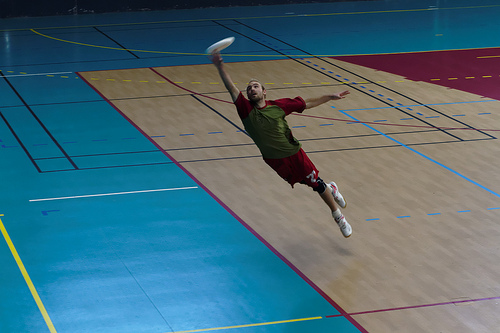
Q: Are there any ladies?
A: No, there are no ladies.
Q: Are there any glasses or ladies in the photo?
A: No, there are no ladies or glasses.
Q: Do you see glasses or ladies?
A: No, there are no ladies or glasses.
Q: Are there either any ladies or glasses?
A: No, there are no ladies or glasses.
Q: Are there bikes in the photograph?
A: No, there are no bikes.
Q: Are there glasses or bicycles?
A: No, there are no bicycles or glasses.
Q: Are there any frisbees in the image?
A: Yes, there is a frisbee.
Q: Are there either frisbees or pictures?
A: Yes, there is a frisbee.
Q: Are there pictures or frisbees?
A: Yes, there is a frisbee.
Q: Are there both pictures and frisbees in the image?
A: No, there is a frisbee but no pictures.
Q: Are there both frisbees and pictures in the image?
A: No, there is a frisbee but no pictures.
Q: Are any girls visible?
A: No, there are no girls.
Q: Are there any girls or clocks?
A: No, there are no girls or clocks.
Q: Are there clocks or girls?
A: No, there are no girls or clocks.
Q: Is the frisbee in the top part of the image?
A: Yes, the frisbee is in the top of the image.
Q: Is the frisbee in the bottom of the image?
A: No, the frisbee is in the top of the image.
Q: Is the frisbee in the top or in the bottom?
A: The frisbee is in the top of the image.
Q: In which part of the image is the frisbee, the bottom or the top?
A: The frisbee is in the top of the image.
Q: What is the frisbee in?
A: The frisbee is in the air.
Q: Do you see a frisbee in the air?
A: Yes, there is a frisbee in the air.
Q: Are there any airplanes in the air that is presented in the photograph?
A: No, there is a frisbee in the air.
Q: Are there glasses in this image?
A: No, there are no glasses.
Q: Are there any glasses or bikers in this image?
A: No, there are no glasses or bikers.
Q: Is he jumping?
A: Yes, the man is jumping.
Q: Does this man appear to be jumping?
A: Yes, the man is jumping.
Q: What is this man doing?
A: The man is jumping.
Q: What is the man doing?
A: The man is jumping.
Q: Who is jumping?
A: The man is jumping.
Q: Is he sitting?
A: No, the man is jumping.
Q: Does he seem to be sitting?
A: No, the man is jumping.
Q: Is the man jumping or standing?
A: The man is jumping.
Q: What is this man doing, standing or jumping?
A: The man is jumping.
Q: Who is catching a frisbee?
A: The man is catching a frisbee.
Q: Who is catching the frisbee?
A: The man is catching a frisbee.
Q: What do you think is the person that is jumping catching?
A: The man is catching a frisbee.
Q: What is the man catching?
A: The man is catching a frisbee.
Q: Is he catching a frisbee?
A: Yes, the man is catching a frisbee.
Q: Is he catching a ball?
A: No, the man is catching a frisbee.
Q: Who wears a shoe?
A: The man wears a shoe.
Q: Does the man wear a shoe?
A: Yes, the man wears a shoe.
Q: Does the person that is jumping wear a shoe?
A: Yes, the man wears a shoe.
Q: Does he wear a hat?
A: No, the man wears a shoe.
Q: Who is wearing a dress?
A: The man is wearing a dress.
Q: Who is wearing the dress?
A: The man is wearing a dress.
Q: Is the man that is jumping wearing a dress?
A: Yes, the man is wearing a dress.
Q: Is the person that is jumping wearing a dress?
A: Yes, the man is wearing a dress.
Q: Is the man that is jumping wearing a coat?
A: No, the man is wearing a dress.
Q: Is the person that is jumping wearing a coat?
A: No, the man is wearing a dress.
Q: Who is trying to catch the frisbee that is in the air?
A: The man is trying to catch the frisbee.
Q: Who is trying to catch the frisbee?
A: The man is trying to catch the frisbee.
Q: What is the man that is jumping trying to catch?
A: The man is trying to catch the frisbee.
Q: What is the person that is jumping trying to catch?
A: The man is trying to catch the frisbee.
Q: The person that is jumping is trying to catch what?
A: The man is trying to catch the frisbee.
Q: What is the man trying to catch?
A: The man is trying to catch the frisbee.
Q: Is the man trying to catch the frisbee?
A: Yes, the man is trying to catch the frisbee.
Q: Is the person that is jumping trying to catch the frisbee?
A: Yes, the man is trying to catch the frisbee.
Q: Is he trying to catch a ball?
A: No, the man is trying to catch the frisbee.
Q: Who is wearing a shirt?
A: The man is wearing a shirt.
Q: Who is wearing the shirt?
A: The man is wearing a shirt.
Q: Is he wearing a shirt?
A: Yes, the man is wearing a shirt.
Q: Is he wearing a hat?
A: No, the man is wearing a shirt.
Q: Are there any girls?
A: No, there are no girls.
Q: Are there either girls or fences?
A: No, there are no girls or fences.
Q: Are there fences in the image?
A: No, there are no fences.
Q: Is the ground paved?
A: Yes, the ground is paved.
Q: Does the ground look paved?
A: Yes, the ground is paved.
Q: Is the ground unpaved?
A: No, the ground is paved.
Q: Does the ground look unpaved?
A: No, the ground is paved.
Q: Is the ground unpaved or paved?
A: The ground is paved.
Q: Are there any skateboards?
A: No, there are no skateboards.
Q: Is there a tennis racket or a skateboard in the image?
A: No, there are no skateboards or rackets.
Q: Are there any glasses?
A: No, there are no glasses.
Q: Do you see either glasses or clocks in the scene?
A: No, there are no glasses or clocks.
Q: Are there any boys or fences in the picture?
A: No, there are no boys or fences.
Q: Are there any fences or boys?
A: No, there are no boys or fences.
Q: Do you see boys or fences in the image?
A: No, there are no fences or boys.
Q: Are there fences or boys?
A: No, there are no fences or boys.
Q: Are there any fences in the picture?
A: No, there are no fences.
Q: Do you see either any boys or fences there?
A: No, there are no fences or boys.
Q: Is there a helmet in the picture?
A: No, there are no helmets.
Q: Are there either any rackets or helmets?
A: No, there are no helmets or rackets.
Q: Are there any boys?
A: No, there are no boys.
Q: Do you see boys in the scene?
A: No, there are no boys.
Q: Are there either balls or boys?
A: No, there are no boys or balls.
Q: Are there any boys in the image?
A: No, there are no boys.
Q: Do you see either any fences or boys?
A: No, there are no boys or fences.